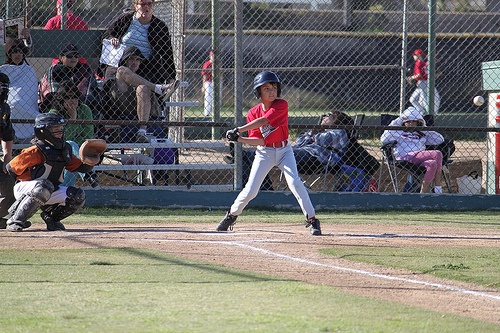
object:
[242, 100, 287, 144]
shirt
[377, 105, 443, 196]
girl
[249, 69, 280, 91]
helmet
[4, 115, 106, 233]
catcher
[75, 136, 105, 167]
glove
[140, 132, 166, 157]
cooler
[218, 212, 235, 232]
cleats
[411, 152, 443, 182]
pants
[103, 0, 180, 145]
man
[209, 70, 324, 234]
boy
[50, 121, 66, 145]
mask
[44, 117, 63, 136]
face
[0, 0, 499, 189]
fence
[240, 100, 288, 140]
jersey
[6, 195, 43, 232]
gear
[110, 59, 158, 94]
leg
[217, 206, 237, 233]
shoe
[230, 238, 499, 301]
line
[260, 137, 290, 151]
belt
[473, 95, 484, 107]
ball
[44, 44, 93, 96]
people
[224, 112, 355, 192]
lady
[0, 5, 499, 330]
game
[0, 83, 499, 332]
action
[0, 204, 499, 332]
field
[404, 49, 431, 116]
player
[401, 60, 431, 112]
uniform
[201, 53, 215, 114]
player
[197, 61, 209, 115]
uniform